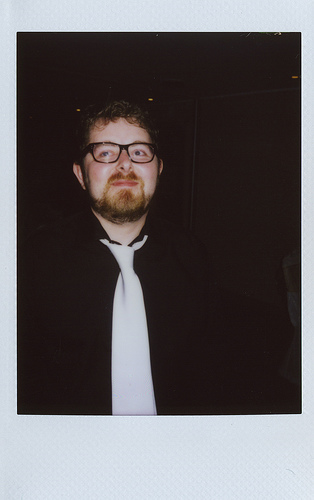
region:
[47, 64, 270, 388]
a man standing up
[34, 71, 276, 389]
a man standing inside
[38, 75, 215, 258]
a man with a beard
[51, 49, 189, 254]
a man with curly hair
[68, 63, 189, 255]
a man wearing glasses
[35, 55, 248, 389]
a man wearing a tie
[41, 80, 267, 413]
a woman wearing white ties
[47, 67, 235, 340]
a woman wearing a shirt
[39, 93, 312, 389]
a woman wearing a black shirt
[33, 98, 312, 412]
a man wearing a shirt and tie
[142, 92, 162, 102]
small light in the ceiling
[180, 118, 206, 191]
frame of brown door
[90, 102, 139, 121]
black curls on man's head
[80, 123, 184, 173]
large black glasses on face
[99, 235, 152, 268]
knot in white tie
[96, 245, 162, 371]
large white tie around man's neck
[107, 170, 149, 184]
brown mustache on face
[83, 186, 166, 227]
full beard on man's face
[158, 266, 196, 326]
man wearing black shirt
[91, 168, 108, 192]
red cheeks on man's face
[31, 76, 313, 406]
a man standing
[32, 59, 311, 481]
a man standing outside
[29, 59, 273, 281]
a man with curly hair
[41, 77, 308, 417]
a man wearing a white tie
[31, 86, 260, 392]
a man wearing a shirt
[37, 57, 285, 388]
a man wearing a black shirt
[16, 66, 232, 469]
a man dressed nicely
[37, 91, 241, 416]
man wearing black framed eyeglasses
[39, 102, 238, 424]
man wearing white necktie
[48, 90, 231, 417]
man with short red curly hair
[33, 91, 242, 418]
man with chubby cheeks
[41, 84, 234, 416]
man with red facial hair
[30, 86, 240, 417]
man wearing a black formal shirt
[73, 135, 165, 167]
black framed eyeglasses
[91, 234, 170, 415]
long white necktie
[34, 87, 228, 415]
man with a smiling expression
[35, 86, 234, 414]
man looking to the left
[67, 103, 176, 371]
Man wearing neck tie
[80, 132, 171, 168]
Man has black glasses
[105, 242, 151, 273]
Knot of silver tie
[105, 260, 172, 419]
Tie is relatively long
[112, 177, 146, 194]
Man's lips are pursed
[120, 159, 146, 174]
Face is somewhat shiny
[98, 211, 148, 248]
Neck is short and white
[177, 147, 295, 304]
Wall behind man is dark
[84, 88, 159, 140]
Brown hair is curly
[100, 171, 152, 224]
Orange beard and mustache